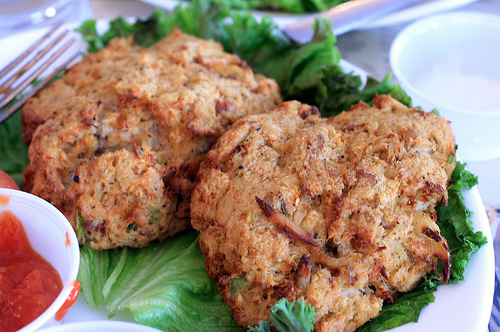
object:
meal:
[27, 37, 459, 330]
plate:
[433, 272, 488, 330]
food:
[17, 9, 457, 330]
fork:
[1, 18, 83, 118]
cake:
[191, 93, 463, 330]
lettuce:
[13, 15, 477, 330]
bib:
[6, 23, 461, 330]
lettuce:
[76, 245, 221, 330]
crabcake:
[192, 94, 456, 328]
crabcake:
[21, 27, 281, 251]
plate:
[0, 12, 496, 330]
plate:
[24, 50, 487, 320]